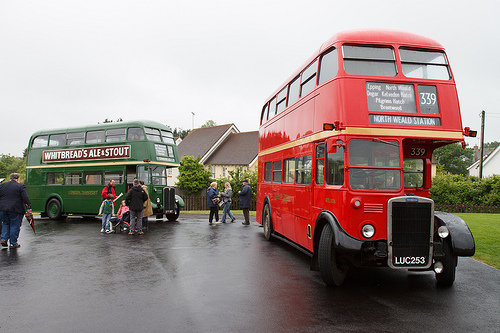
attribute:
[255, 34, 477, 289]
bus — red, large, double decker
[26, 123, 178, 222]
bus — green, double decker, red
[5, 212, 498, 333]
pavement — wet, here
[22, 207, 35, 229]
umbrella — colorful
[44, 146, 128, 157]
sign — whitbread's ale, st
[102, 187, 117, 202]
jacket — red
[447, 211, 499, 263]
lawn — manicured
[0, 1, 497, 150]
sky — overcast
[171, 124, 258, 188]
house — brown, white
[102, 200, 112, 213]
vest — green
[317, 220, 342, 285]
wheel — here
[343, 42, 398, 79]
window — here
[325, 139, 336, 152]
mirror — here, side